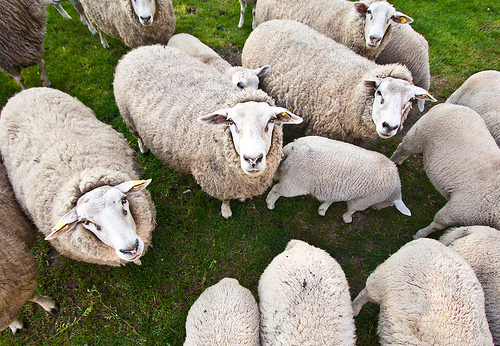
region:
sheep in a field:
[39, 28, 414, 331]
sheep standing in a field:
[43, 54, 428, 332]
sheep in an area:
[64, 58, 454, 344]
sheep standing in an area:
[94, 41, 476, 311]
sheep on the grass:
[27, 27, 444, 343]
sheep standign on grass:
[72, 36, 338, 341]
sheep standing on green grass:
[100, 50, 477, 287]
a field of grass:
[62, 48, 489, 340]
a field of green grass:
[22, 19, 434, 344]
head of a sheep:
[205, 94, 306, 188]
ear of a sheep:
[39, 213, 91, 250]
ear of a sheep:
[120, 170, 170, 201]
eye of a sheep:
[80, 213, 99, 230]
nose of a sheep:
[117, 238, 147, 270]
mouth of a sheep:
[120, 239, 166, 268]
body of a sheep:
[92, 21, 266, 158]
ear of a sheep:
[413, 91, 440, 101]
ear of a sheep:
[353, 5, 370, 14]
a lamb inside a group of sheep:
[265, 135, 412, 224]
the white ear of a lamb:
[392, 199, 411, 217]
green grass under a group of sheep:
[2, 0, 498, 341]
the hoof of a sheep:
[40, 292, 56, 317]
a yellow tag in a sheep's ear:
[395, 15, 406, 25]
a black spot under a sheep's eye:
[120, 205, 130, 215]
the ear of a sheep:
[116, 173, 155, 196]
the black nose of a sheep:
[381, 118, 400, 133]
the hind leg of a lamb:
[265, 178, 301, 210]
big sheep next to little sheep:
[129, 44, 288, 181]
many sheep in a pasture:
[71, 29, 497, 263]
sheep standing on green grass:
[35, 95, 434, 305]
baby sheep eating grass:
[299, 138, 411, 229]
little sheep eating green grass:
[300, 134, 412, 244]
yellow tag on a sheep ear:
[272, 108, 308, 133]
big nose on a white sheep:
[241, 152, 268, 176]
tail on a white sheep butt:
[277, 233, 323, 290]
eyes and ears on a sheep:
[211, 106, 329, 145]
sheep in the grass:
[7, 4, 479, 344]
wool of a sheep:
[123, 62, 194, 116]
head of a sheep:
[193, 98, 300, 183]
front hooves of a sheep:
[3, 287, 64, 343]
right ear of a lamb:
[391, 197, 414, 222]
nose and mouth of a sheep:
[112, 239, 149, 263]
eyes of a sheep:
[367, 84, 422, 109]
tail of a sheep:
[445, 222, 472, 244]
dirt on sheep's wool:
[298, 267, 315, 294]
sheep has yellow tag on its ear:
[111, 41, 303, 219]